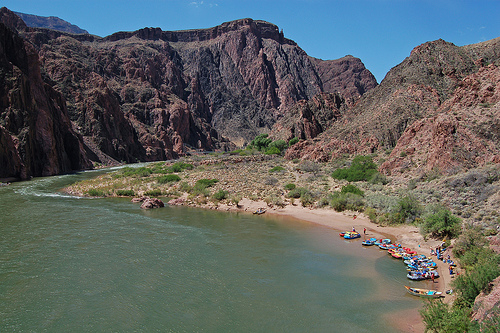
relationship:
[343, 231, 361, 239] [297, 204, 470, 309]
boat sitting on beach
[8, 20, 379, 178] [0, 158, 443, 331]
cliff near water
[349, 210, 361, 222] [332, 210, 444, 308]
person standing near boats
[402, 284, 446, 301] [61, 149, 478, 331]
boat next to beach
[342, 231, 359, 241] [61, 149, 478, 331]
boat next to beach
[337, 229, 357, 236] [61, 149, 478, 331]
boat next to beach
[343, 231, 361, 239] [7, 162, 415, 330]
boat on water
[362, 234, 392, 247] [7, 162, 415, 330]
boats on water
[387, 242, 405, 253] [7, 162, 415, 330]
boats on water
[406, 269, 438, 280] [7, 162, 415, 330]
boats on water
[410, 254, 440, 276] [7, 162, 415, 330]
boats on water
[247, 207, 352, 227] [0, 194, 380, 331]
sand by water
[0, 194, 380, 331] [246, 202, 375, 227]
water by sand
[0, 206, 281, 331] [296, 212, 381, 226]
water by sand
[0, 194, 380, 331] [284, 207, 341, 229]
water by sand